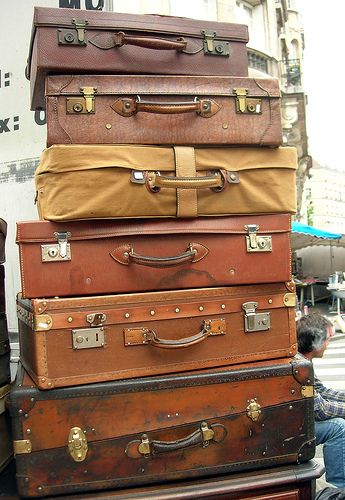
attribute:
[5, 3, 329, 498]
suitcases — stacked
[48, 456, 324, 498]
stand — is wooden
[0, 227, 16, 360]
table — brown , wooden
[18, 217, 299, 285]
suitcase — is old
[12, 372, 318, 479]
suitcase — large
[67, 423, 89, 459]
gold latch — is gold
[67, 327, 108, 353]
metal hook — is metal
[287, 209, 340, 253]
canopy — is blue, is white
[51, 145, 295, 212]
suitcase — yellow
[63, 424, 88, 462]
latch — is gold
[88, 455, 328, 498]
wooden table — is wooden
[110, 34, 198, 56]
handle — is brown, is leather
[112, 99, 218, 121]
handle — is brown, is leather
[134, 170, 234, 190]
handle — is brown, is leather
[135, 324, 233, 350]
handle — is brown, is leather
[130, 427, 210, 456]
handle — is brown, is leather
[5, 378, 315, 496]
brown case — is worn, is brown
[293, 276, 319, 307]
table — is gray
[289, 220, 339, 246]
canopy — is aqua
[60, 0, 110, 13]
black letters — is black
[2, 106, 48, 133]
black letters — is white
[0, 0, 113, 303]
wall — is white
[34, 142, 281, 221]
case — fabric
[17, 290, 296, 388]
suitcase — is old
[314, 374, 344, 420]
shirt — green, white, check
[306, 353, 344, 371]
lne — is white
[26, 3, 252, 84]
suitcase — vintage, bottom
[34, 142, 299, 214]
suitcase — tan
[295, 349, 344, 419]
shirt — blue, plaid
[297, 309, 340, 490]
man — seated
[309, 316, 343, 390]
lines — are white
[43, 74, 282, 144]
suitcase — is old, is old-fashioned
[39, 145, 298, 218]
suitcase — yellow, fourth from bottom, is old, is old-fashioned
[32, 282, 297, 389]
suitcase — orange, second from bottom, is old-fashioned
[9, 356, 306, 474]
case — bottom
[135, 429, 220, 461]
handle — old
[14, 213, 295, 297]
suitcase — third from bottom, leather, tan, is old-fashioned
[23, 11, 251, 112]
suitcase — smallest, is old, is old-fashioned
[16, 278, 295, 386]
case — is brown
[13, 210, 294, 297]
case — is tan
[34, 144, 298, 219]
case — is brown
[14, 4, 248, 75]
case — is brown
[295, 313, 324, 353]
hair — grey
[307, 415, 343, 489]
jeans — are blue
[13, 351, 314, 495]
case — is brown